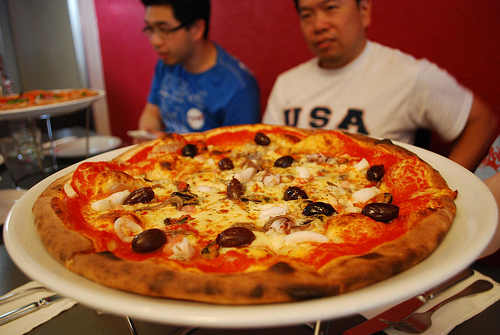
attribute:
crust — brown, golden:
[74, 212, 459, 305]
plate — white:
[47, 130, 125, 158]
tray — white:
[2, 123, 493, 329]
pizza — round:
[33, 124, 459, 305]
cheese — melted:
[79, 133, 401, 267]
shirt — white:
[261, 38, 479, 150]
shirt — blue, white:
[143, 42, 262, 131]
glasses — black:
[139, 22, 195, 39]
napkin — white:
[358, 270, 500, 335]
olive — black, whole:
[275, 154, 297, 167]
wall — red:
[96, 3, 500, 158]